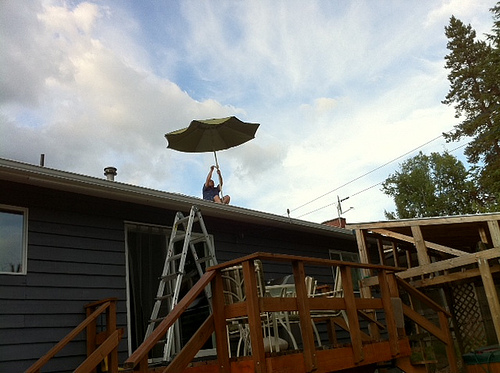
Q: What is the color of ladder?
A: White.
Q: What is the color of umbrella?
A: Black.